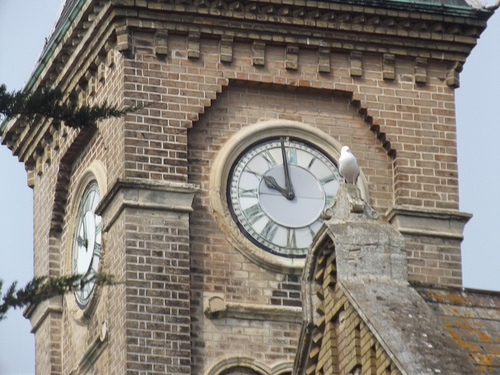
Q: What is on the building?
A: A clock.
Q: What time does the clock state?
A: Ten o'clock.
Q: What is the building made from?
A: Bricks.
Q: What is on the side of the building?
A: A green tree branch.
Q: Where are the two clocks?
A: On the building.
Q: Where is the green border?
A: On top of the building.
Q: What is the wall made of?
A: Brick.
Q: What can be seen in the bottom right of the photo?
A: A roof.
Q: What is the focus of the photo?
A: A brick tower with clocks set inward.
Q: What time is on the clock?
A: Almost 10:00.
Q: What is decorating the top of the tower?
A: Bricks and stone.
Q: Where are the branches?
A: Extending toward the building.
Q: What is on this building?
A: A clock.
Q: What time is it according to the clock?
A: 9:59 AM.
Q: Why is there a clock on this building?
A: To show the time.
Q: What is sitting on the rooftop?
A: A bird.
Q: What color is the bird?
A: White.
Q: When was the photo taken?
A: During the day.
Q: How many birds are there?
A: One.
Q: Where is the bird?
A: On the rooftop peak.